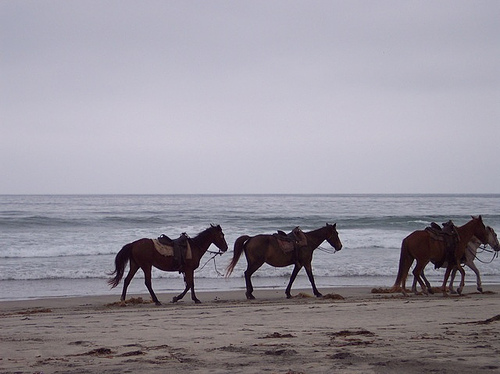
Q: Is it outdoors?
A: Yes, it is outdoors.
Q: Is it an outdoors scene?
A: Yes, it is outdoors.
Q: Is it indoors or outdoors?
A: It is outdoors.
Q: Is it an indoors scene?
A: No, it is outdoors.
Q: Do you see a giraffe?
A: No, there are no giraffes.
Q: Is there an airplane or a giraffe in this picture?
A: No, there are no giraffes or airplanes.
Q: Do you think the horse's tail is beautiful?
A: Yes, the tail is beautiful.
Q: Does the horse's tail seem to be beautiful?
A: Yes, the tail is beautiful.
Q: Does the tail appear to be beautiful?
A: Yes, the tail is beautiful.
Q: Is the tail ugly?
A: No, the tail is beautiful.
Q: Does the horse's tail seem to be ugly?
A: No, the tail is beautiful.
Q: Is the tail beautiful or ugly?
A: The tail is beautiful.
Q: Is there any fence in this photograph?
A: No, there are no fences.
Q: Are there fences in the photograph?
A: No, there are no fences.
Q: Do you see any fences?
A: No, there are no fences.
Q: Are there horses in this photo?
A: Yes, there is a horse.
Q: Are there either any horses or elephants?
A: Yes, there is a horse.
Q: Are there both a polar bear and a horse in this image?
A: No, there is a horse but no polar bears.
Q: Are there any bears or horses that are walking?
A: Yes, the horse is walking.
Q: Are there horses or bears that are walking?
A: Yes, the horse is walking.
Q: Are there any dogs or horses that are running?
A: Yes, the horse is running.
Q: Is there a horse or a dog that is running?
A: Yes, the horse is running.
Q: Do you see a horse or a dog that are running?
A: Yes, the horse is running.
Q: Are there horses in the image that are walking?
A: Yes, there is a horse that is walking.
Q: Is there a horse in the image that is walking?
A: Yes, there is a horse that is walking.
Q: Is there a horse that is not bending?
A: Yes, there is a horse that is walking.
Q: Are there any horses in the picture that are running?
A: Yes, there is a horse that is running.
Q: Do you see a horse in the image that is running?
A: Yes, there is a horse that is running.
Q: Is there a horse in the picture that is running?
A: Yes, there is a horse that is running.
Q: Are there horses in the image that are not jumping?
A: Yes, there is a horse that is running.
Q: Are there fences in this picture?
A: No, there are no fences.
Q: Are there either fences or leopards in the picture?
A: No, there are no fences or leopards.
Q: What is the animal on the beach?
A: The animal is a horse.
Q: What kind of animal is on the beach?
A: The animal is a horse.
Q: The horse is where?
A: The horse is on the beach.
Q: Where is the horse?
A: The horse is on the beach.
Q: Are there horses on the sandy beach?
A: Yes, there is a horse on the beach.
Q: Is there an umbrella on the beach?
A: No, there is a horse on the beach.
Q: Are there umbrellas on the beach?
A: No, there is a horse on the beach.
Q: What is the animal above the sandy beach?
A: The animal is a horse.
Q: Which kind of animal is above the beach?
A: The animal is a horse.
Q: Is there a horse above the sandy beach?
A: Yes, there is a horse above the beach.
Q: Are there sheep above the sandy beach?
A: No, there is a horse above the beach.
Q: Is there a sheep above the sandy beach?
A: No, there is a horse above the beach.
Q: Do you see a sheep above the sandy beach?
A: No, there is a horse above the beach.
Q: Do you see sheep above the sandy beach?
A: No, there is a horse above the beach.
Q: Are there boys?
A: No, there are no boys.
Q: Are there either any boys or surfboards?
A: No, there are no boys or surfboards.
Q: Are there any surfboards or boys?
A: No, there are no boys or surfboards.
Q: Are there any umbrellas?
A: No, there are no umbrellas.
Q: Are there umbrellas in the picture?
A: No, there are no umbrellas.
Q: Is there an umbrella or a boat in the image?
A: No, there are no umbrellas or boats.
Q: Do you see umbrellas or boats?
A: No, there are no umbrellas or boats.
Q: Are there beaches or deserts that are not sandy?
A: No, there is a beach but it is sandy.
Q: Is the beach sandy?
A: Yes, the beach is sandy.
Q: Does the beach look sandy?
A: Yes, the beach is sandy.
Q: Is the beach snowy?
A: No, the beach is sandy.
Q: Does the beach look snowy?
A: No, the beach is sandy.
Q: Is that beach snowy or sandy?
A: The beach is sandy.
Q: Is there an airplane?
A: No, there are no airplanes.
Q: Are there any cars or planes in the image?
A: No, there are no planes or cars.